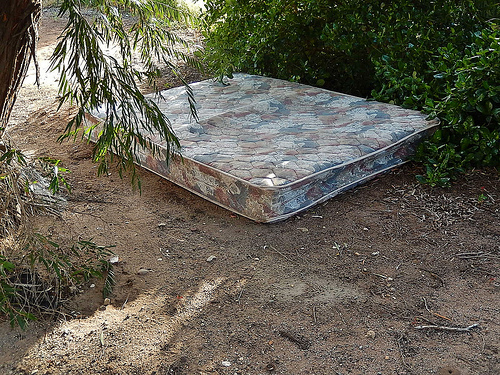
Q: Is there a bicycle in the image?
A: No, there are no bicycles.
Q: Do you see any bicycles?
A: No, there are no bicycles.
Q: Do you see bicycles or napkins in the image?
A: No, there are no bicycles or napkins.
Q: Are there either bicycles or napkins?
A: No, there are no bicycles or napkins.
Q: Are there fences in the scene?
A: No, there are no fences.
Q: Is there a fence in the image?
A: No, there are no fences.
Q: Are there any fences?
A: No, there are no fences.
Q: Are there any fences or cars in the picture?
A: No, there are no fences or cars.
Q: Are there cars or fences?
A: No, there are no fences or cars.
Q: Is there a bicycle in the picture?
A: No, there are no bicycles.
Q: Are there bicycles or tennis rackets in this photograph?
A: No, there are no bicycles or tennis rackets.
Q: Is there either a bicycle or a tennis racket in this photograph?
A: No, there are no bicycles or rackets.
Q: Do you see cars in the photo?
A: No, there are no cars.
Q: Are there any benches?
A: No, there are no benches.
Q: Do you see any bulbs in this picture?
A: No, there are no bulbs.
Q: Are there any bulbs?
A: No, there are no bulbs.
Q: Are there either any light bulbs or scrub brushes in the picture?
A: No, there are no light bulbs or scrub brushes.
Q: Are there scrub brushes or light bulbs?
A: No, there are no light bulbs or scrub brushes.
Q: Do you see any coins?
A: No, there are no coins.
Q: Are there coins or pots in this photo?
A: No, there are no coins or pots.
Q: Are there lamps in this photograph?
A: No, there are no lamps.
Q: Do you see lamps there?
A: No, there are no lamps.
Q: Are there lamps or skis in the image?
A: No, there are no lamps or skis.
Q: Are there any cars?
A: No, there are no cars.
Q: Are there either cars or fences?
A: No, there are no cars or fences.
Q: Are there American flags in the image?
A: No, there are no American flags.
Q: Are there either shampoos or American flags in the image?
A: No, there are no American flags or shampoos.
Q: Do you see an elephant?
A: No, there are no elephants.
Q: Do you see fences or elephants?
A: No, there are no elephants or fences.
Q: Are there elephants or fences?
A: No, there are no elephants or fences.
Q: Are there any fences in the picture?
A: No, there are no fences.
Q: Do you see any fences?
A: No, there are no fences.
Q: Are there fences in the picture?
A: No, there are no fences.